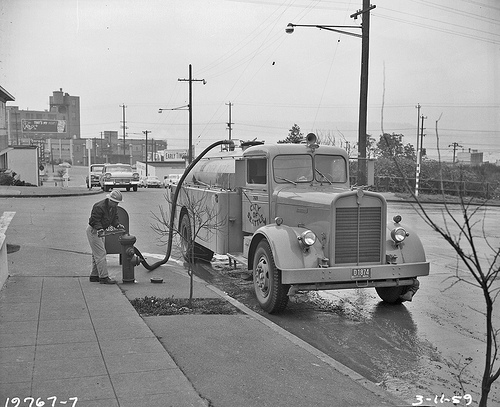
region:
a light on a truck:
[301, 228, 318, 248]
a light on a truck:
[389, 222, 409, 243]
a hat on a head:
[102, 189, 121, 203]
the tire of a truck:
[245, 227, 292, 321]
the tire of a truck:
[175, 210, 199, 265]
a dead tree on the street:
[152, 182, 232, 334]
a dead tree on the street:
[359, 83, 496, 401]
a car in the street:
[98, 159, 135, 189]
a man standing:
[79, 186, 129, 286]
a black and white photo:
[3, 2, 494, 403]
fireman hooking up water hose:
[66, 166, 163, 307]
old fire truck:
[128, 122, 429, 337]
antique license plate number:
[343, 259, 384, 289]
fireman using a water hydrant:
[63, 106, 348, 328]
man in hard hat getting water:
[71, 159, 185, 294]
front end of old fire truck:
[236, 136, 446, 303]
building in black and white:
[10, 72, 105, 177]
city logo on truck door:
[232, 187, 272, 234]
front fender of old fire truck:
[324, 182, 391, 294]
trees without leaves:
[342, 59, 499, 392]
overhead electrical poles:
[210, 32, 293, 81]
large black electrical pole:
[106, 94, 148, 161]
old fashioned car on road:
[99, 155, 144, 190]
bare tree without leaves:
[408, 179, 498, 381]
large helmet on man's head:
[103, 180, 130, 206]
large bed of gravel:
[134, 288, 247, 331]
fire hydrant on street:
[113, 235, 155, 285]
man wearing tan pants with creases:
[75, 220, 117, 278]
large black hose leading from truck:
[130, 137, 254, 274]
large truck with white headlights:
[143, 111, 434, 320]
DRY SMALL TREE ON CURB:
[149, 170, 232, 307]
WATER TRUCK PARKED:
[170, 135, 430, 310]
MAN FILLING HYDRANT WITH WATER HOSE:
[76, 136, 234, 283]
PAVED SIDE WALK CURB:
[0, 238, 364, 402]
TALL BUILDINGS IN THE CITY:
[0, 85, 162, 190]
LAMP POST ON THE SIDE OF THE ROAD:
[283, 9, 384, 181]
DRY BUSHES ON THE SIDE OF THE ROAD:
[353, 155, 498, 200]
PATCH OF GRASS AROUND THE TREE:
[139, 291, 244, 314]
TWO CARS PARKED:
[85, 160, 141, 192]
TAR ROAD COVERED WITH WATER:
[0, 185, 497, 402]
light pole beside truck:
[281, 0, 381, 187]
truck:
[160, 127, 432, 313]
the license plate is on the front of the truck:
[351, 264, 373, 281]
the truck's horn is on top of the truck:
[295, 130, 320, 154]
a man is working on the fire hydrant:
[85, 182, 141, 288]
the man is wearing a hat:
[105, 182, 125, 204]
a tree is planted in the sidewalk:
[130, 170, 242, 320]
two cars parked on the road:
[82, 156, 146, 191]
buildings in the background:
[0, 80, 195, 185]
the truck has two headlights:
[295, 220, 410, 246]